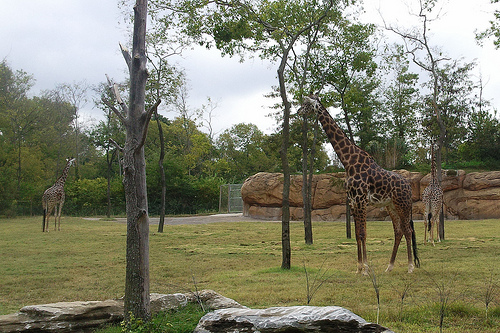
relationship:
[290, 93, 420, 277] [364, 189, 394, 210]
giraffe has stomach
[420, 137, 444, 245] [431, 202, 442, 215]
giraffe has stomach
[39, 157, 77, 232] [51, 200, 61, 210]
giraffe has stomach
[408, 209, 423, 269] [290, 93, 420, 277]
tail of giraffe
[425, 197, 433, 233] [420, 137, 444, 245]
tail of giraffe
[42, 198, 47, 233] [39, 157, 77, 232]
tail of giraffe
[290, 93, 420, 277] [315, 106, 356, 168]
giraffe has neck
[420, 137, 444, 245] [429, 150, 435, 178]
giraffe has neck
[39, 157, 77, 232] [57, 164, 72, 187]
giraffe has neck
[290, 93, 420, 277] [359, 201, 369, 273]
giraffe has leg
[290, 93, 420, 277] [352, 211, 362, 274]
giraffe has leg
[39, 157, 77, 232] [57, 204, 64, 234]
giraffe has leg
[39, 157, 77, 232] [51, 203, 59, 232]
giraffe has leg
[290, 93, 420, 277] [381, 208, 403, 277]
giraffe has leg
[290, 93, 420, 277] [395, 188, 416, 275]
giraffe has leg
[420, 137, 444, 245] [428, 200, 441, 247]
giraffe has leg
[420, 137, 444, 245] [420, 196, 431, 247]
giraffe has leg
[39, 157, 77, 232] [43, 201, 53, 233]
giraffe has leg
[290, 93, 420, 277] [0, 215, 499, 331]
giraffe on grass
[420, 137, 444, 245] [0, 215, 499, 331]
giraffe on grass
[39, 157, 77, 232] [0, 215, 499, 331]
giraffe on grass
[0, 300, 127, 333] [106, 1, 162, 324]
large rock near trunk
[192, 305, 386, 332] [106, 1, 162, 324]
large rock near trunk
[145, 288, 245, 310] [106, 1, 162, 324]
large rock near trunk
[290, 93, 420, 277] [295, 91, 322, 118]
giraffe has face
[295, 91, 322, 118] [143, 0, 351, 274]
face near tree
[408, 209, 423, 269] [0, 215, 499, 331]
tail touching grass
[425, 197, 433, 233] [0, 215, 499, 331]
tail touching grass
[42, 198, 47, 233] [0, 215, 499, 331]
tail touching grass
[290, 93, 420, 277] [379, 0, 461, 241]
giraffe in front of tree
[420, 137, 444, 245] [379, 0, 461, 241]
giraffe in front of tree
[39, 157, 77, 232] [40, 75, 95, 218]
giraffe in front of tree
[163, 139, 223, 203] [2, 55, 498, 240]
green leaves on trees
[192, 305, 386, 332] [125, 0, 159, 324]
large rock around tree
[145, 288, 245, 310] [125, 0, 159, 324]
large rock around tree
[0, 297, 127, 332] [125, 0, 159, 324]
large rock around tree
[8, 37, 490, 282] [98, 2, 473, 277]
many trees are delicate trees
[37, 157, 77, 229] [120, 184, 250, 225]
giraffe near enclosure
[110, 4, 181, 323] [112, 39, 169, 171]
tree has branch stumps